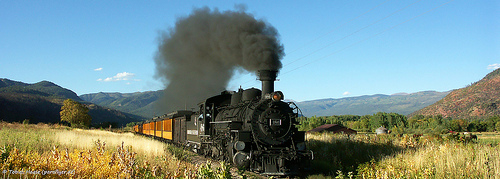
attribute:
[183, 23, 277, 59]
smoke — black, gray, heavy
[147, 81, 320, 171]
train — black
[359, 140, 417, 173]
ground — green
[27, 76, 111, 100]
mountains — big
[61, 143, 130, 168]
grass — tall, tan, long, yellow, brown, dry, green, short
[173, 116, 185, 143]
car — black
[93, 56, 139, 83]
clouds — white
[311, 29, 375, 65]
sky — blue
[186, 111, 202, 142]
train car — black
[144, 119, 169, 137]
cargo — orange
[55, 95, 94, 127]
tree — green, big